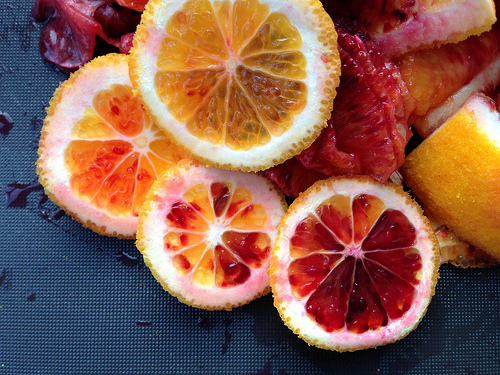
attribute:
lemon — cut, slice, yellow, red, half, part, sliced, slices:
[128, 1, 343, 173]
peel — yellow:
[198, 147, 278, 171]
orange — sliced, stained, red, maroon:
[269, 178, 441, 353]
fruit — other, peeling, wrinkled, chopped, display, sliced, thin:
[340, 28, 416, 182]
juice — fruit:
[5, 178, 45, 209]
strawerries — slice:
[25, 0, 148, 70]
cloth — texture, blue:
[0, 333, 89, 373]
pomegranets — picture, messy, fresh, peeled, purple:
[346, 1, 498, 85]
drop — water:
[0, 111, 16, 143]